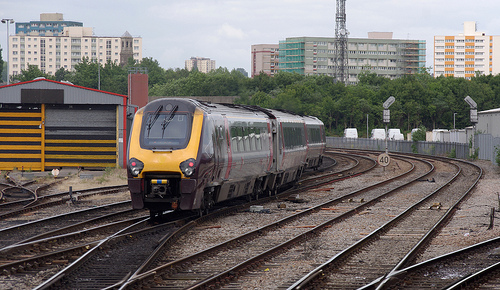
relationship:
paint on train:
[131, 108, 204, 175] [126, 96, 325, 209]